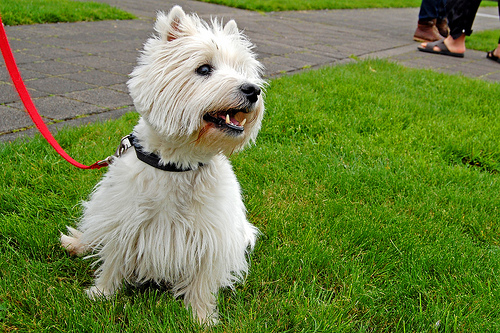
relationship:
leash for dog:
[1, 22, 114, 170] [61, 3, 261, 327]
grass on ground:
[293, 107, 467, 287] [302, 78, 433, 331]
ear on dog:
[157, 1, 195, 50] [40, 19, 324, 316]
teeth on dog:
[223, 113, 231, 124] [61, 3, 261, 327]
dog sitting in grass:
[61, 3, 261, 327] [1, 143, 482, 331]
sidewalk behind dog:
[3, 0, 493, 168] [52, 0, 297, 330]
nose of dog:
[235, 76, 264, 106] [50, 4, 320, 329]